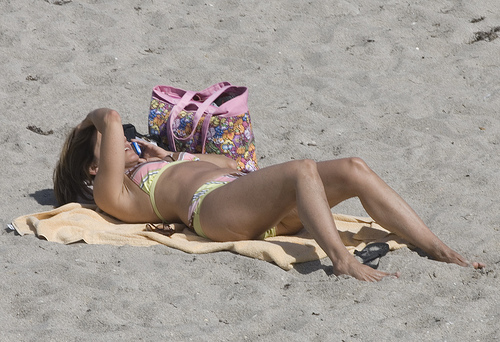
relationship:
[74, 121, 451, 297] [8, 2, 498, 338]
lady on beach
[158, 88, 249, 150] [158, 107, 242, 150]
purse has design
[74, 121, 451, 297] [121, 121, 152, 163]
lady on phone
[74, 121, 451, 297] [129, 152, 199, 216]
lady wearing bathing suit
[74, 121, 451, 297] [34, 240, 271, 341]
lady on sand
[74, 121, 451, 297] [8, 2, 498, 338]
lady in beach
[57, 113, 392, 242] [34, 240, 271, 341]
woman in sand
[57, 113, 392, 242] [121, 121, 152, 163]
woman on phone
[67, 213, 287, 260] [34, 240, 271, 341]
towel keeps out sand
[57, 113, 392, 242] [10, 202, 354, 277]
woman on blanket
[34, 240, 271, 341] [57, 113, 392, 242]
sand around woman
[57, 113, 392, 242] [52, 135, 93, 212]
woman has hair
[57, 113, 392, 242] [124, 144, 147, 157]
woman on cellphone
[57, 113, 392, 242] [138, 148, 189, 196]
woman wears clothing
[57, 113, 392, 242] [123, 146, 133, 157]
woman opens mouth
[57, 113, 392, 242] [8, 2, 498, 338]
woman on beach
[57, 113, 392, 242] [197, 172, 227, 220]
woman wears bikini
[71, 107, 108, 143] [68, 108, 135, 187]
hand on head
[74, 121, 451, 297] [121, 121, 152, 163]
girl by phone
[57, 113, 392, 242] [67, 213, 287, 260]
woman on towel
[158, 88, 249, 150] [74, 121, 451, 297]
bag next to girl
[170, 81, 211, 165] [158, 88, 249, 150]
handles of bag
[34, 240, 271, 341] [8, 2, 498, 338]
sand on beach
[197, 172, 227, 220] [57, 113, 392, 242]
bikini on woman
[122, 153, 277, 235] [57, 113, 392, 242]
body on woman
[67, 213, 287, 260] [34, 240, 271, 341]
towel on sand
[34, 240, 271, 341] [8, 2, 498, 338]
sand of beach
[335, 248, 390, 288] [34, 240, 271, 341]
foot in sand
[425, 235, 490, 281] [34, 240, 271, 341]
foot in sand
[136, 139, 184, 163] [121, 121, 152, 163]
hand on phone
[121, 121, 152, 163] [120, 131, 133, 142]
phone against ear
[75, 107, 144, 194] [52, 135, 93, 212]
arm touching hair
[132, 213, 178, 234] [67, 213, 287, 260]
sunglasses on towel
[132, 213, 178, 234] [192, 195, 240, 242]
sunglasses next to hip